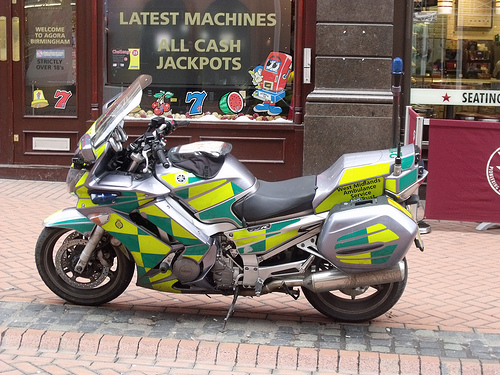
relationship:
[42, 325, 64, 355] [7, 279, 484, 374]
brick on road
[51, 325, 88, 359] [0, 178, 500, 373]
brick on road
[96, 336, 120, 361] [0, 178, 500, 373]
brick on road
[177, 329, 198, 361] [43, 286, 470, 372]
red brick on road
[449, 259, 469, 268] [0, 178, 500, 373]
brick on road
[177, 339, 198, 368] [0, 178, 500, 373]
red brick on road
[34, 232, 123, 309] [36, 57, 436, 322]
tire of bike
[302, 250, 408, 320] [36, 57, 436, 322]
back tire of bike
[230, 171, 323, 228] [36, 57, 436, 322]
seat on bike